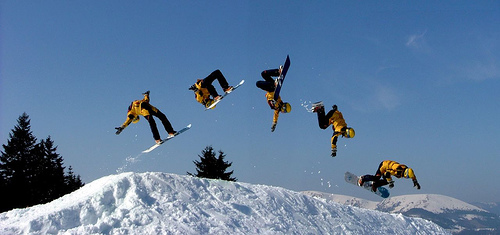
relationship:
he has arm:
[107, 82, 196, 162] [118, 122, 133, 135]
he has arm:
[107, 82, 196, 162] [137, 84, 155, 104]